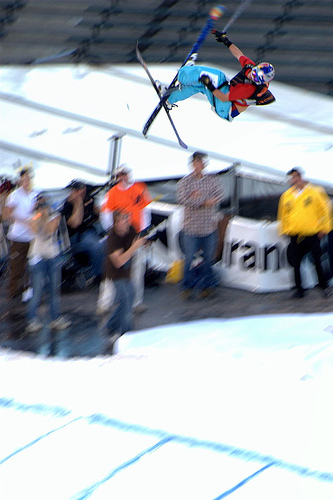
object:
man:
[176, 151, 226, 297]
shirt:
[174, 173, 222, 237]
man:
[278, 169, 332, 298]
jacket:
[278, 185, 331, 238]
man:
[104, 213, 155, 338]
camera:
[137, 220, 169, 241]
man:
[5, 169, 33, 301]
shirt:
[7, 188, 33, 243]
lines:
[1, 396, 333, 499]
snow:
[2, 350, 331, 499]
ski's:
[135, 3, 227, 149]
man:
[166, 30, 276, 120]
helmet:
[250, 61, 277, 86]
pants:
[166, 64, 230, 119]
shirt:
[228, 57, 257, 112]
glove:
[213, 29, 231, 46]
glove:
[198, 75, 213, 91]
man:
[109, 170, 153, 228]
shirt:
[109, 184, 144, 233]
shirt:
[105, 227, 134, 277]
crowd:
[0, 153, 329, 333]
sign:
[101, 196, 296, 294]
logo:
[142, 210, 171, 253]